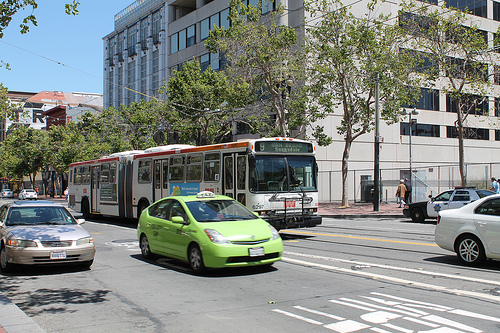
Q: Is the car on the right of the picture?
A: Yes, the car is on the right of the image.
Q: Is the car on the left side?
A: No, the car is on the right of the image.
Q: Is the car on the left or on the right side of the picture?
A: The car is on the right of the image.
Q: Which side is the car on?
A: The car is on the right of the image.